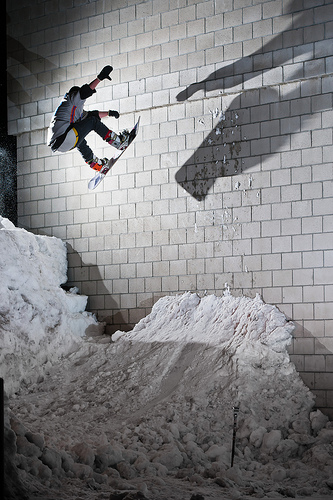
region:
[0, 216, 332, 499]
White snow on ground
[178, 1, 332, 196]
A man's shadow on a wall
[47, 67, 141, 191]
A man on a snow board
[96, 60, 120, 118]
A man wearing gloves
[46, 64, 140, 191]
A man in midair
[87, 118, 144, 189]
A snowboard in midair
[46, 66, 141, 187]
Snowboarder in the air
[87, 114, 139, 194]
Snow board in the air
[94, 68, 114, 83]
Black mitten on man's hand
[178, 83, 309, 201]
Shadow of a man snowboarding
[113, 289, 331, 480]
Snow piled against a wall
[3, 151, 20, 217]
Tree on side of building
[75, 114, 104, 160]
Black pants on a snow boarder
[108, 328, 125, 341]
Small lump of snow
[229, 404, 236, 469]
Pole sticking up from ground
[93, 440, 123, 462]
Round clump of snow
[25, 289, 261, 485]
the huge mound of snow on the ground.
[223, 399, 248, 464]
the stick in the snow.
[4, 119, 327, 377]
The wall that is made of bricks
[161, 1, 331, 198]
The shadow of the snowboarder.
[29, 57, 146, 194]
The snowboarder is riding on the snow.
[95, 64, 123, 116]
The snowboarder has black gloves.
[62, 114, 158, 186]
The snow board that the man is on.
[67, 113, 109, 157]
The pants the snowboarder is wearing.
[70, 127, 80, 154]
The yellow belt the man is wearing.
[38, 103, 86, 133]
The shirt the snowboarder is wearing.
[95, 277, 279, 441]
Ramp made of snow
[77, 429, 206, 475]
Boulders of snow on the ground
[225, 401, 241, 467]
pole in the snow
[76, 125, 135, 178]
person wearing snow boots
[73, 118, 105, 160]
person wearing gray pants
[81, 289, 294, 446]
ramp made of snow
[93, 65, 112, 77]
person wearing a black glove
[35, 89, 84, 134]
person wearing a gray shirt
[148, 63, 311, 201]
shadow on the wall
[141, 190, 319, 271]
wall made of bricks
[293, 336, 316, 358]
white brick on wall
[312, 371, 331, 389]
white brick on wall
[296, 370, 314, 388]
white brick on wall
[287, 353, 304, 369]
white brick on wall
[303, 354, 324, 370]
white brick on wall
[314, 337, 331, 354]
white brick on wall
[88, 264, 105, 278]
white brick on wall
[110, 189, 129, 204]
white brick on wall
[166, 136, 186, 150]
white brick on wall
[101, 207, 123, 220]
white brick on wall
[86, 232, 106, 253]
white brick on wall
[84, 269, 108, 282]
white brick on wall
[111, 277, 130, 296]
white brick on wall